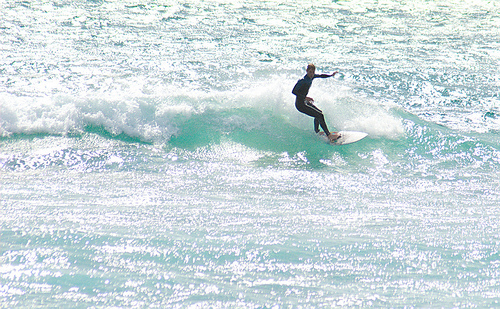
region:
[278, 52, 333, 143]
surfer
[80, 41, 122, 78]
white and green ocean waves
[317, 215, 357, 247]
white and green ocean waves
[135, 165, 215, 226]
white and green ocean waves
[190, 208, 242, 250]
white and green ocean waves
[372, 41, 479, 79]
white and green ocean waves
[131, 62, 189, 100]
white and green ocean waves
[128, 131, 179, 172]
white and green ocean waves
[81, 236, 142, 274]
white and green ocean waves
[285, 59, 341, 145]
this is a person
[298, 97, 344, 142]
this is a person's leg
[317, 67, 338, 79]
this is a person's hand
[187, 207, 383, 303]
this is a body of water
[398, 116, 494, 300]
this is a body of water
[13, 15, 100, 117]
this is a body of water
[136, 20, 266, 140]
this is a body of water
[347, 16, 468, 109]
this is a body of water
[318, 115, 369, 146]
this is a surfing board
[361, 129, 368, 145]
There is a white surfboard that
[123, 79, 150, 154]
There are rough waves here that are visible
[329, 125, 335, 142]
This man has bare feet on a surfboard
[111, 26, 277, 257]
This photo has a great deal of detail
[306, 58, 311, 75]
This man has a head full of brown hair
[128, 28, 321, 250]
This photo has a great deal of detail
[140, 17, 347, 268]
This photo is really quite lovely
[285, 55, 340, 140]
a person on a surfboard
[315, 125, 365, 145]
a white surfboard on the water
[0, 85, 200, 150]
a wave crashing down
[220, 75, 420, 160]
A cresting wave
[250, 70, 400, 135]
A splash of water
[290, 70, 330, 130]
a black wet suit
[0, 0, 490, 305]
A large body of water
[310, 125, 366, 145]
A white surfboard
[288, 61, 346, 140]
a man in a wet suit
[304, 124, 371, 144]
a surfboard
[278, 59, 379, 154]
A young man surfing a wave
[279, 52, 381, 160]
A young man surfing a wave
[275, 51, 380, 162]
A young man surfing a wave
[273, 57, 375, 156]
A young man surfing a wave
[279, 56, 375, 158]
A young man surfing a wave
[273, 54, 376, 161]
A young man surfing a wave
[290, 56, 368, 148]
man surfing on the water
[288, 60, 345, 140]
black wet suit on the man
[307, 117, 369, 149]
white surfboard on the water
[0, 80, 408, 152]
white splashes of water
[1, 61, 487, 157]
wave on the water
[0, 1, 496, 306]
water covering the surface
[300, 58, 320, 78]
short hair on the man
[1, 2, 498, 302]
ripples on the water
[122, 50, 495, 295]
a body of water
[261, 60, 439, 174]
a man on a surfboard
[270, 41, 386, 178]
a surfer wearing a wetsuit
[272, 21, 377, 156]
a surfer wearing a black wetsuit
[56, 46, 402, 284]
a body of water with waves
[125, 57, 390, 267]
a body of blue water